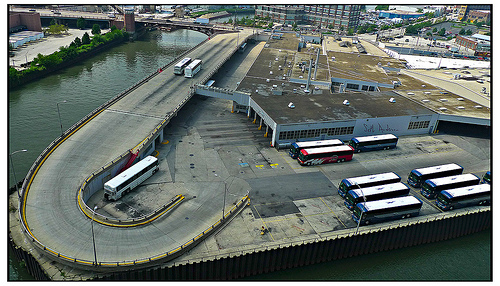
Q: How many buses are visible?
A: 12.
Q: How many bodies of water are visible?
A: Two.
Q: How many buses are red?
A: One.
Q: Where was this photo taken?
A: Above a parking lot.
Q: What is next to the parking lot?
A: A body of water.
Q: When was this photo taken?
A: Outside, during the daytime.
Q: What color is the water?
A: Green-blue.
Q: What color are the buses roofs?
A: White.